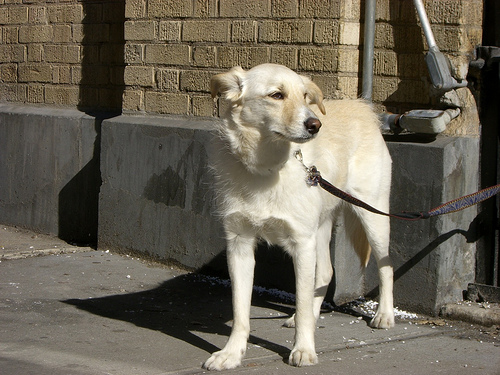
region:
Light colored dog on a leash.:
[205, 62, 393, 374]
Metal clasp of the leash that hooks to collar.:
[290, 146, 317, 184]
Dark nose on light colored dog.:
[302, 115, 322, 135]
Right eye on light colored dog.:
[267, 87, 282, 99]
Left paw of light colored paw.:
[290, 341, 320, 366]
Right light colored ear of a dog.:
[207, 63, 249, 99]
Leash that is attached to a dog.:
[316, 172, 498, 218]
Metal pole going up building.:
[358, 0, 375, 107]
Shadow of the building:
[57, 161, 102, 246]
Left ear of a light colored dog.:
[299, 72, 324, 117]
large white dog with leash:
[184, 57, 416, 363]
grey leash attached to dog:
[296, 148, 499, 228]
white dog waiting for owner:
[188, 52, 413, 359]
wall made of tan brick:
[6, 4, 85, 96]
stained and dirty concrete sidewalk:
[6, 240, 128, 364]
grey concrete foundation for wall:
[95, 112, 199, 267]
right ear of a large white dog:
[206, 61, 253, 106]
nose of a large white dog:
[275, 98, 324, 145]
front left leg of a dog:
[283, 227, 321, 370]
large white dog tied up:
[186, 60, 415, 373]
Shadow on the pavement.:
[59, 255, 309, 374]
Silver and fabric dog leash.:
[257, 149, 494, 251]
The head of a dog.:
[192, 52, 342, 159]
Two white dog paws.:
[139, 332, 338, 372]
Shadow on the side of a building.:
[28, 38, 154, 307]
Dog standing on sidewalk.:
[99, 61, 424, 371]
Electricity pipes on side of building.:
[362, 19, 469, 162]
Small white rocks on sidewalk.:
[82, 240, 454, 368]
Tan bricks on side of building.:
[0, 0, 358, 58]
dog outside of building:
[105, 25, 461, 371]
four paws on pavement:
[170, 296, 427, 371]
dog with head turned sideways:
[187, 40, 347, 200]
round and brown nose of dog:
[255, 61, 345, 153]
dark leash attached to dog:
[275, 117, 490, 237]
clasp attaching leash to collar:
[270, 135, 322, 187]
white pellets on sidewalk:
[170, 265, 416, 365]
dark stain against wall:
[130, 141, 232, 231]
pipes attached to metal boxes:
[356, 20, 476, 140]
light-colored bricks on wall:
[135, 21, 241, 91]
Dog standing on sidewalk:
[195, 97, 405, 290]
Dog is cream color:
[216, 110, 361, 262]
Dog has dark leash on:
[211, 87, 400, 229]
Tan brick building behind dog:
[81, 47, 185, 92]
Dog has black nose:
[296, 112, 318, 142]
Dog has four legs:
[190, 264, 408, 339]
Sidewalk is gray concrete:
[62, 256, 334, 368]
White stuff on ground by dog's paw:
[346, 288, 416, 328]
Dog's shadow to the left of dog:
[82, 241, 208, 354]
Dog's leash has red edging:
[379, 189, 499, 213]